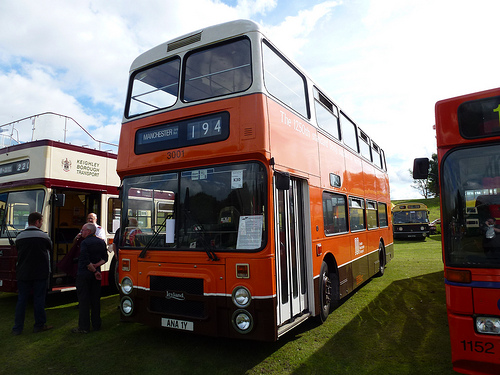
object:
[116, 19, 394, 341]
bus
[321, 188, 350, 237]
windows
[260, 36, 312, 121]
windows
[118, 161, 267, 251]
windshield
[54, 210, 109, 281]
people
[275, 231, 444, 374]
grass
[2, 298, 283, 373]
grass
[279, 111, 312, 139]
lettering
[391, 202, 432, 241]
bus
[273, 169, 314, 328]
door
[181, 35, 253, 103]
window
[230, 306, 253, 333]
headlights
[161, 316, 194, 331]
license plate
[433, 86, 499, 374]
bus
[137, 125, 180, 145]
sign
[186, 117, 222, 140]
number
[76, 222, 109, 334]
man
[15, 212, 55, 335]
man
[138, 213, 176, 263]
windshield wipers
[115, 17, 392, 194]
top level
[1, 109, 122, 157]
observation roof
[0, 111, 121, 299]
bus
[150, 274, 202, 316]
grill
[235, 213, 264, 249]
paper